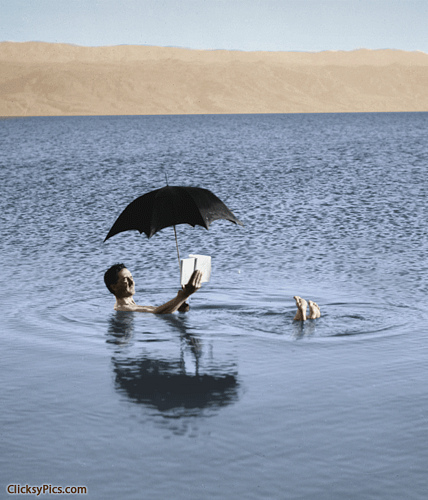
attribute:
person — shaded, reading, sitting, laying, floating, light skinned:
[104, 260, 323, 326]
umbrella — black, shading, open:
[103, 171, 240, 312]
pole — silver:
[163, 169, 181, 269]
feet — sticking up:
[290, 293, 321, 327]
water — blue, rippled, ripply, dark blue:
[2, 114, 423, 498]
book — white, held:
[176, 252, 214, 292]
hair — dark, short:
[101, 260, 129, 298]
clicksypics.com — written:
[4, 480, 92, 498]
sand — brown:
[2, 40, 427, 117]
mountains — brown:
[2, 38, 427, 120]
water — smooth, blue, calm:
[6, 338, 427, 498]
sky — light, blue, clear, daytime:
[2, 3, 427, 57]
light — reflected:
[5, 274, 426, 448]